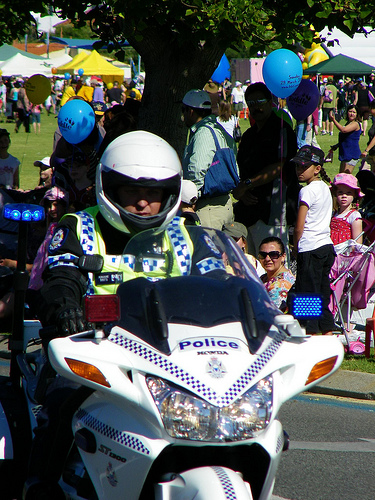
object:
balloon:
[261, 47, 303, 102]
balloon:
[57, 100, 97, 147]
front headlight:
[147, 376, 272, 438]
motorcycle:
[3, 241, 348, 498]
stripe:
[67, 327, 282, 496]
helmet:
[93, 129, 184, 237]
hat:
[291, 143, 324, 163]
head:
[295, 158, 318, 181]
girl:
[295, 144, 332, 334]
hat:
[331, 173, 365, 198]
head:
[336, 184, 357, 209]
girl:
[325, 167, 363, 248]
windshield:
[120, 215, 260, 292]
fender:
[163, 438, 263, 500]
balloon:
[304, 44, 331, 65]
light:
[293, 294, 322, 317]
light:
[84, 294, 122, 323]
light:
[64, 353, 112, 389]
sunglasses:
[247, 99, 274, 108]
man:
[234, 80, 293, 220]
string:
[275, 97, 290, 246]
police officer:
[41, 129, 276, 357]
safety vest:
[70, 205, 195, 297]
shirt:
[298, 183, 332, 252]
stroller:
[328, 237, 374, 360]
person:
[184, 88, 243, 239]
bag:
[189, 126, 239, 201]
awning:
[51, 48, 124, 86]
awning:
[3, 53, 51, 80]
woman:
[321, 106, 367, 170]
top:
[338, 122, 364, 160]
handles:
[49, 304, 87, 339]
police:
[178, 333, 240, 354]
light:
[305, 355, 337, 389]